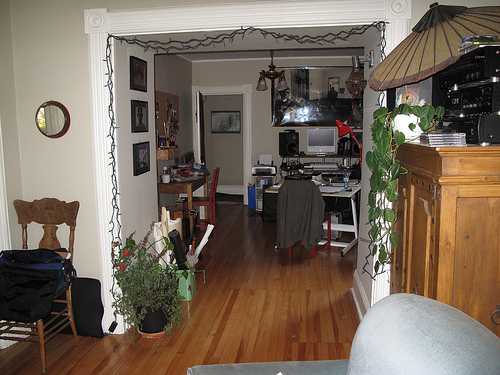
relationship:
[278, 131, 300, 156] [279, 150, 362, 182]
speaker on desk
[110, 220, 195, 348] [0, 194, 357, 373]
plant on floor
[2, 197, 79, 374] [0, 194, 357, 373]
chair on floor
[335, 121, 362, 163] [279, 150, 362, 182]
lamp over desk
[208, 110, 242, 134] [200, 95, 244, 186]
picture on wall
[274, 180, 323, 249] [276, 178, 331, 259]
jacket on chair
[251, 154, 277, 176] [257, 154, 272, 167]
printer with paper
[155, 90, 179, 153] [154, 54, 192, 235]
bulletin board on wall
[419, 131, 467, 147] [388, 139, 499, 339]
cds on hutch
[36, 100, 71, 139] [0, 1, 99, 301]
mirror on wall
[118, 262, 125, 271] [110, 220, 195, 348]
flower on plant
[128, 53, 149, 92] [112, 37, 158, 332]
picture on wall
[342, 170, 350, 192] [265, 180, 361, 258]
water bottle on desk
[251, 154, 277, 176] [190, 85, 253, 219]
printer by doorway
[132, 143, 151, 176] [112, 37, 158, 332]
picture on wall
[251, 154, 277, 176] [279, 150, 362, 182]
printer near desk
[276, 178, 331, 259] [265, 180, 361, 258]
chair under desk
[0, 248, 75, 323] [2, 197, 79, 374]
bag on chair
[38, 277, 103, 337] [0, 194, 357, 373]
bag on floor